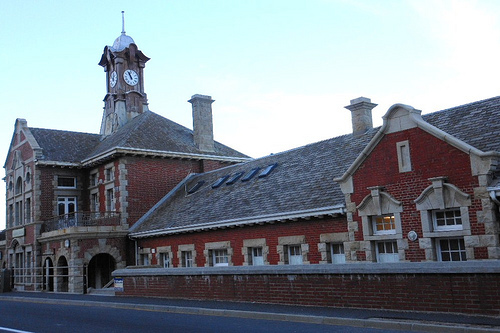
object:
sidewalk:
[7, 288, 498, 326]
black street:
[0, 300, 393, 330]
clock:
[123, 69, 141, 86]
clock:
[109, 69, 118, 88]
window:
[435, 237, 462, 260]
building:
[0, 11, 497, 328]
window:
[371, 213, 394, 233]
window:
[372, 240, 401, 261]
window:
[432, 208, 459, 230]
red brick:
[363, 168, 387, 182]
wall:
[253, 283, 342, 302]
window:
[275, 235, 310, 265]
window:
[236, 240, 270, 266]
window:
[203, 239, 237, 267]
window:
[173, 244, 196, 269]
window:
[153, 246, 175, 268]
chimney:
[187, 93, 217, 153]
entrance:
[54, 253, 70, 293]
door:
[55, 192, 76, 229]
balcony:
[42, 205, 127, 236]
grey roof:
[280, 167, 335, 203]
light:
[377, 216, 395, 229]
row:
[170, 236, 350, 267]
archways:
[80, 244, 125, 297]